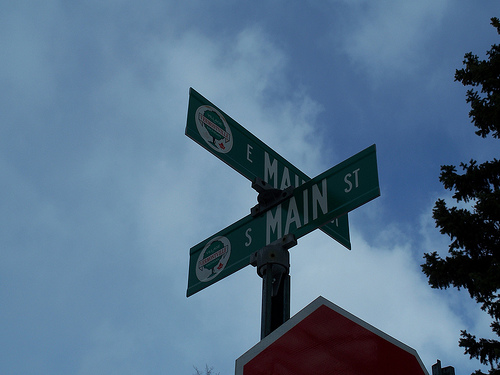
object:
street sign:
[182, 85, 351, 248]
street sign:
[187, 139, 383, 291]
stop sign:
[231, 294, 426, 374]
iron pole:
[254, 230, 292, 339]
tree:
[416, 12, 499, 374]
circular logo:
[193, 104, 234, 152]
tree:
[203, 108, 228, 149]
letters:
[198, 111, 230, 138]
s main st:
[239, 160, 368, 249]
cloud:
[1, 1, 500, 375]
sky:
[1, 1, 500, 375]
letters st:
[344, 169, 362, 194]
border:
[234, 294, 428, 375]